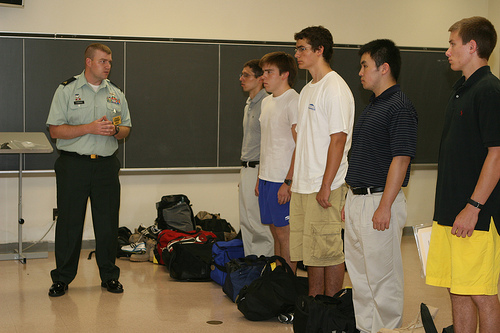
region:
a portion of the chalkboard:
[148, 53, 208, 150]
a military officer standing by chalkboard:
[40, 45, 138, 298]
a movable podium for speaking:
[0, 135, 48, 260]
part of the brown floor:
[25, 298, 137, 332]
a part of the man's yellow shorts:
[435, 232, 495, 286]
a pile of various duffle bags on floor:
[158, 196, 226, 280]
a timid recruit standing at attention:
[343, 39, 415, 331]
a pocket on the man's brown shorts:
[305, 218, 343, 265]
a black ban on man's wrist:
[463, 199, 484, 210]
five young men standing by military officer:
[27, 0, 497, 330]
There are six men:
[48, 18, 498, 323]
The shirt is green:
[46, 71, 131, 155]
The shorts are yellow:
[424, 215, 499, 295]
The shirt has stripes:
[347, 92, 417, 189]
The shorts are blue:
[258, 178, 290, 228]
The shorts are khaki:
[287, 187, 344, 270]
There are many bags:
[146, 193, 341, 328]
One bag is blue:
[213, 242, 245, 277]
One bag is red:
[151, 230, 222, 255]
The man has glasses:
[290, 34, 349, 294]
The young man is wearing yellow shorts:
[423, 15, 499, 332]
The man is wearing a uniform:
[45, 41, 130, 295]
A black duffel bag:
[294, 289, 354, 331]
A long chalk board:
[1, 30, 467, 166]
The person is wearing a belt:
[341, 36, 416, 331]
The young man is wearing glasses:
[236, 59, 272, 259]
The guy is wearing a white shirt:
[288, 24, 355, 301]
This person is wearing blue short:
[256, 50, 300, 272]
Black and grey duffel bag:
[156, 193, 196, 234]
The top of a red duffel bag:
[154, 227, 218, 254]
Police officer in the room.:
[33, 46, 180, 308]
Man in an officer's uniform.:
[38, 36, 158, 314]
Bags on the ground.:
[150, 200, 300, 330]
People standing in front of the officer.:
[203, 31, 486, 294]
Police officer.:
[27, 45, 194, 270]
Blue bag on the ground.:
[203, 237, 253, 304]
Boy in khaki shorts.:
[254, 160, 374, 287]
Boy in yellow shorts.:
[423, 202, 498, 279]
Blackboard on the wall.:
[131, 24, 251, 188]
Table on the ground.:
[5, 115, 77, 280]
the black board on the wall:
[0, 32, 499, 173]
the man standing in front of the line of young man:
[45, 43, 131, 295]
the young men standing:
[235, 15, 498, 331]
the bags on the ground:
[117, 194, 454, 331]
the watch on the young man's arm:
[465, 197, 483, 210]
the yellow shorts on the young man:
[425, 214, 498, 294]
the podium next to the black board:
[0, 132, 54, 264]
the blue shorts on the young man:
[257, 178, 290, 226]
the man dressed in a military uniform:
[46, 44, 131, 296]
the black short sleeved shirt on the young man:
[432, 64, 498, 235]